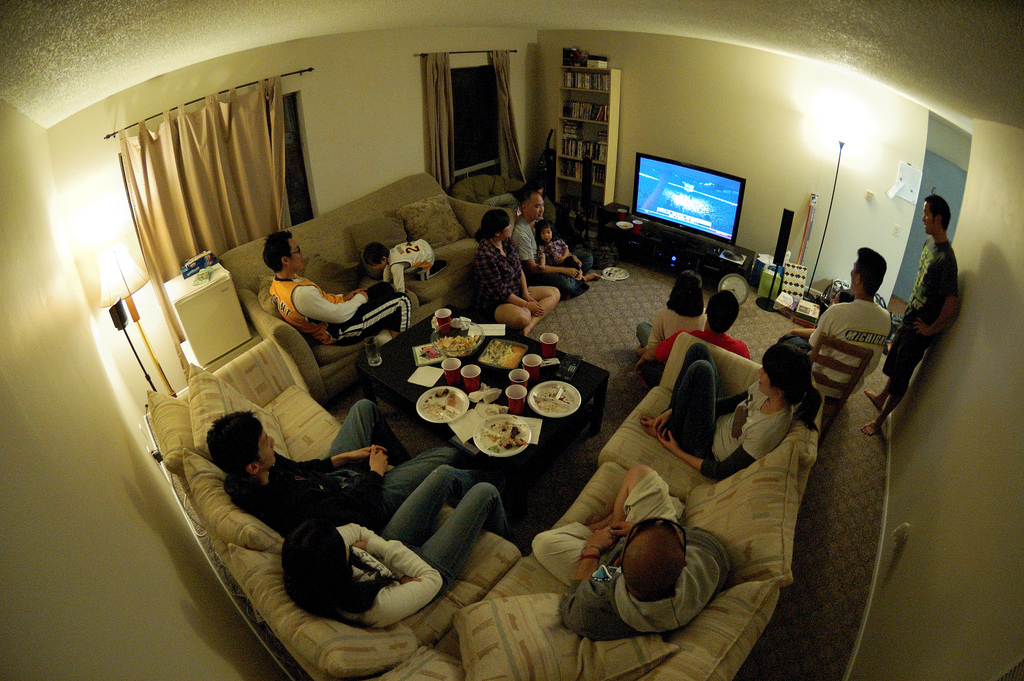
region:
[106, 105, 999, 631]
many people in the room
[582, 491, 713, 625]
head of the man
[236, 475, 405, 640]
head of the girl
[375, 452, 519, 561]
blue pants on girl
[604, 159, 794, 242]
television that is turned on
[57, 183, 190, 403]
light in the room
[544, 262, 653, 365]
rug in the room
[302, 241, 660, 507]
food and drink on table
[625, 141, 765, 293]
an LCD television screen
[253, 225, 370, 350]
a male wearing a yellow jersey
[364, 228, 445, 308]
a child crawling on a couch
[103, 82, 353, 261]
a curtain hanging from a rod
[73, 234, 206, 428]
a corner lamp shade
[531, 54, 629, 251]
a book shelf in the corner of a room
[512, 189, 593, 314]
a man holding a young girl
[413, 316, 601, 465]
plastic cups with disposable plates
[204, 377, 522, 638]
a male and a female sitting on a couch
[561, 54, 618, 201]
tall bookshelf with books on it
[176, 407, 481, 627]
man and woman sitting on sofa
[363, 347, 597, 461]
black coffee table with plates on it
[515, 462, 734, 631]
man sitting cross legged on sofa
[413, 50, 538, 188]
a window with curtains open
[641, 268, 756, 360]
couple sitting on the floor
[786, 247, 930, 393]
man sitting in a chair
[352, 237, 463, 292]
a baby crawling on couch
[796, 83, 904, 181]
light from lamp shining on the wall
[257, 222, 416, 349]
Man wearing black pants with white stripes.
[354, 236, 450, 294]
Boy wearing a white basketball jersey.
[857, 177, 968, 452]
Man leaning against a wall.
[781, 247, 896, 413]
Man wearing a white shirt.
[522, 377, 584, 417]
Empty white plastic plate.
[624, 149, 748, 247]
Black television with a blue screen.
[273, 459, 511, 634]
Woman sitting with her arms crossed.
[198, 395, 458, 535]
Man wearing blue jeans.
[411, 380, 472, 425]
Empty white plastic plate.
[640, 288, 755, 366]
Man wearing a red shirt.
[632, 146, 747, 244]
a large flatscreen TV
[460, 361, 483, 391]
a red plastic cup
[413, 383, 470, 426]
A plate made for dining.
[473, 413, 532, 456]
A plate made for dining.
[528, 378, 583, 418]
A plate made for dining.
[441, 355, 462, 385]
A vessel made for drinking.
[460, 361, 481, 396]
A vessel made for drinking.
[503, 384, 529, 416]
A vessel made for drinking.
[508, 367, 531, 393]
A vessel made for drinking.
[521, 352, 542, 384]
A vessel made for drinking.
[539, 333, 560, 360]
A vessel made for drinking.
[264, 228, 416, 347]
A person sitting down.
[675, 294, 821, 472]
a person sitting down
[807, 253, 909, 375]
a person sitting down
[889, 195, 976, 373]
a person sitting down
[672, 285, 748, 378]
a person sitting down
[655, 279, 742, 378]
a person sitting down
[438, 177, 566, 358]
a person sitting down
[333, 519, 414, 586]
a person sitting down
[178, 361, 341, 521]
a person sitting down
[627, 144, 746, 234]
large plasma tv in the room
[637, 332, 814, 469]
person sitting on the sofa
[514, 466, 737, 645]
person sitting on sofa